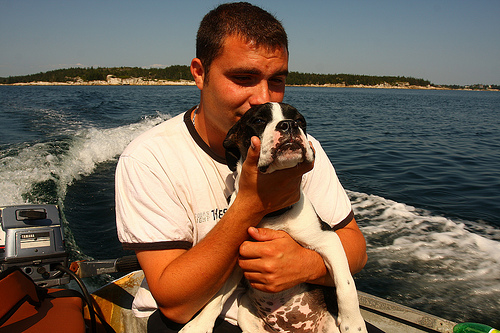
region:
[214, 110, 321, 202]
black and white dog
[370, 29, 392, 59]
white clouds in blue sky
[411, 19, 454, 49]
white clouds in blue sky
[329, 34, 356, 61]
white clouds in blue sky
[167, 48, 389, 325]
a man hodling a dog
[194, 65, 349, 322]
a dog on a boat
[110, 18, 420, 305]
a man on a boat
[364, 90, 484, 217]
a body of water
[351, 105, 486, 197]
a body of calm water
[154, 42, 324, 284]
a man wearing a shirt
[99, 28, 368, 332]
a man wearing a white shirt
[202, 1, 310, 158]
a man with dark hair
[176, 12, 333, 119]
head of the man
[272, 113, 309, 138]
nose of the dog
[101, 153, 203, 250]
sleeve of the shirt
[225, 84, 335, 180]
dark and light face of dog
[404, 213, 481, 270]
white water next to boat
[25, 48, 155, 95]
trees in the distance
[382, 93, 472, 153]
calm water near the boat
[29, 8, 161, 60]
sky with no clouds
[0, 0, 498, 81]
clear blue daytime sky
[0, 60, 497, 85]
trees on strip of land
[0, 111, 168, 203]
wake behind moving boat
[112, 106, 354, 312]
white shirt with black trim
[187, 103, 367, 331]
front of black and white dog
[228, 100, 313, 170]
black nose on dog face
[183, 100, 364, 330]
dog with freckles on stomach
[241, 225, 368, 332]
dog leg over man's arm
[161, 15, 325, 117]
head of the man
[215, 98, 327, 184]
head of the dog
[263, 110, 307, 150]
nose of the dog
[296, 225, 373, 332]
leg of the dog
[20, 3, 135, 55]
blue sky with no clouds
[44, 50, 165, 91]
trees in the distance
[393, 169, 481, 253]
water next to boat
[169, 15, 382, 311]
a man holding a dog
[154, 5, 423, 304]
a man on a boat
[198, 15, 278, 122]
a man that is smiling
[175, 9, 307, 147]
the head of a man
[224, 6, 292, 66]
the hair of a man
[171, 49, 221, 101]
the ear of a man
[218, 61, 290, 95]
the eyes of a man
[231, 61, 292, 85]
the eyebrows of a man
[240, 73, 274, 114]
the nose of a man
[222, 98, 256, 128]
the mouth of a man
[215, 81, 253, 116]
the cheek of a man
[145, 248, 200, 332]
the elbow of a man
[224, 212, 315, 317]
the hand of a man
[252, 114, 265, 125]
Eye on a face.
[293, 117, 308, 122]
Eye on a face.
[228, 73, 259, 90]
Eye on a face.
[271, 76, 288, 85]
Eye on a face.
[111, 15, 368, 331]
A person is sitting down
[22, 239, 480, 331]
A boat on the water.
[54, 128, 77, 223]
A wave in the water.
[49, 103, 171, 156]
A wave in the water.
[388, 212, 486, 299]
A wave in the water.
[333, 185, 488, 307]
A wave in the water.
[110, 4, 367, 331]
man holding a cute puppy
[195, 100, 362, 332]
cute puppy in the boat